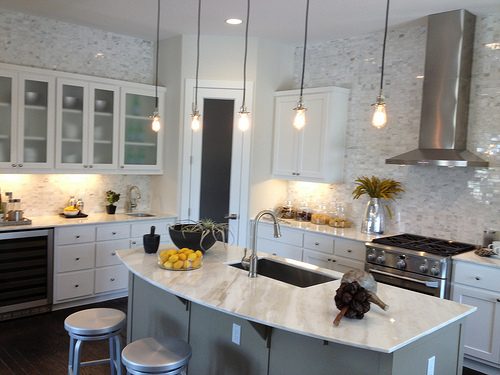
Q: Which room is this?
A: It is a kitchen.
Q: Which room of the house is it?
A: It is a kitchen.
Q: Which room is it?
A: It is a kitchen.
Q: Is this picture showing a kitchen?
A: Yes, it is showing a kitchen.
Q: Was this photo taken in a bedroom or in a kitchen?
A: It was taken at a kitchen.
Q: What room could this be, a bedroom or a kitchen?
A: It is a kitchen.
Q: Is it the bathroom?
A: No, it is the kitchen.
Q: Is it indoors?
A: Yes, it is indoors.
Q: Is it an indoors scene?
A: Yes, it is indoors.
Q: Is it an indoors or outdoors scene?
A: It is indoors.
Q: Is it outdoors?
A: No, it is indoors.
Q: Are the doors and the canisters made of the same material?
A: Yes, both the doors and the canisters are made of glass.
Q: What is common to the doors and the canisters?
A: The material, both the doors and the canisters are glass.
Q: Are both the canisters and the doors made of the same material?
A: Yes, both the canisters and the doors are made of glass.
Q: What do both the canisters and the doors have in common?
A: The material, both the canisters and the doors are glass.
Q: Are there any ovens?
A: Yes, there is an oven.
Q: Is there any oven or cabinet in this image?
A: Yes, there is an oven.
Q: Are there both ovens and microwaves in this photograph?
A: No, there is an oven but no microwaves.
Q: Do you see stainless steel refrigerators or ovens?
A: Yes, there is a stainless steel oven.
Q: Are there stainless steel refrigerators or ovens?
A: Yes, there is a stainless steel oven.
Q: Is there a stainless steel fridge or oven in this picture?
A: Yes, there is a stainless steel oven.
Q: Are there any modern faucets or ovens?
A: Yes, there is a modern oven.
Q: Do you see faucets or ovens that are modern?
A: Yes, the oven is modern.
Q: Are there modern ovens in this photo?
A: Yes, there is a modern oven.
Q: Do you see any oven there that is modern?
A: Yes, there is an oven that is modern.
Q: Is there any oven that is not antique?
A: Yes, there is an modern oven.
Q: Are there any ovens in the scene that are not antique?
A: Yes, there is an modern oven.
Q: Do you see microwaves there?
A: No, there are no microwaves.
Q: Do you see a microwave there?
A: No, there are no microwaves.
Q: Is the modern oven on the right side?
A: Yes, the oven is on the right of the image.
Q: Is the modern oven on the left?
A: No, the oven is on the right of the image.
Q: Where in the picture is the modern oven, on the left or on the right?
A: The oven is on the right of the image.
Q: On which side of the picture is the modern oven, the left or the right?
A: The oven is on the right of the image.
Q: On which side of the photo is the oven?
A: The oven is on the right of the image.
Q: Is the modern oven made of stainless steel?
A: Yes, the oven is made of stainless steel.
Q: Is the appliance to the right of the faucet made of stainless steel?
A: Yes, the oven is made of stainless steel.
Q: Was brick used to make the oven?
A: No, the oven is made of stainless steel.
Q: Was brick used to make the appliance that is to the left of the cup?
A: No, the oven is made of stainless steel.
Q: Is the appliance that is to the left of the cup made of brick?
A: No, the oven is made of stainless steel.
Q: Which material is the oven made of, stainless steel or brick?
A: The oven is made of stainless steel.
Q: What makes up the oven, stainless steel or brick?
A: The oven is made of stainless steel.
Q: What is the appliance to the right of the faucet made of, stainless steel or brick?
A: The oven is made of stainless steel.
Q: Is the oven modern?
A: Yes, the oven is modern.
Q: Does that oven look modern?
A: Yes, the oven is modern.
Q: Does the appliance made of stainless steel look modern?
A: Yes, the oven is modern.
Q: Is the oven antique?
A: No, the oven is modern.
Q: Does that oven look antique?
A: No, the oven is modern.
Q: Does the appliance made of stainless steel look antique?
A: No, the oven is modern.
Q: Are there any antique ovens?
A: No, there is an oven but it is modern.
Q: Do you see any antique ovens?
A: No, there is an oven but it is modern.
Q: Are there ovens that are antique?
A: No, there is an oven but it is modern.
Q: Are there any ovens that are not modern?
A: No, there is an oven but it is modern.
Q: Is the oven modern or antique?
A: The oven is modern.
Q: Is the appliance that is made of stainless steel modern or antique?
A: The oven is modern.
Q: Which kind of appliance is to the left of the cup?
A: The appliance is an oven.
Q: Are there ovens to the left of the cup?
A: Yes, there is an oven to the left of the cup.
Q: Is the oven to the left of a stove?
A: No, the oven is to the left of the cup.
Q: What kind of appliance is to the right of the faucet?
A: The appliance is an oven.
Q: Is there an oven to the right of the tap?
A: Yes, there is an oven to the right of the tap.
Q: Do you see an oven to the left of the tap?
A: No, the oven is to the right of the tap.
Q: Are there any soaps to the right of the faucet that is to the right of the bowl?
A: No, there is an oven to the right of the tap.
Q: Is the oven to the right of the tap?
A: Yes, the oven is to the right of the tap.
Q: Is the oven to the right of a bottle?
A: No, the oven is to the right of the tap.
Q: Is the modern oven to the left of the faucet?
A: No, the oven is to the right of the faucet.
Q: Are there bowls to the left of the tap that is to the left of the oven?
A: Yes, there is a bowl to the left of the tap.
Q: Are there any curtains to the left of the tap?
A: No, there is a bowl to the left of the tap.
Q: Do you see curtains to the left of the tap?
A: No, there is a bowl to the left of the tap.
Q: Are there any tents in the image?
A: No, there are no tents.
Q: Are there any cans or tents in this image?
A: No, there are no tents or cans.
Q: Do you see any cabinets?
A: Yes, there is a cabinet.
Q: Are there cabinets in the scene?
A: Yes, there is a cabinet.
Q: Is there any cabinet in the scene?
A: Yes, there is a cabinet.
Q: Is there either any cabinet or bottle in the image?
A: Yes, there is a cabinet.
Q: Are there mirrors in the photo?
A: No, there are no mirrors.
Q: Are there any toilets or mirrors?
A: No, there are no mirrors or toilets.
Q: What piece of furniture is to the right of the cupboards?
A: The piece of furniture is a cabinet.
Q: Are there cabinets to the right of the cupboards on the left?
A: Yes, there is a cabinet to the right of the cupboards.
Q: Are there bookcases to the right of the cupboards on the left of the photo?
A: No, there is a cabinet to the right of the cupboards.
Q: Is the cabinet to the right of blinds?
A: No, the cabinet is to the right of the cupboards.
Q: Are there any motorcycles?
A: No, there are no motorcycles.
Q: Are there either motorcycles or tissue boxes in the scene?
A: No, there are no motorcycles or tissue boxes.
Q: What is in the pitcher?
A: The plant is in the pitcher.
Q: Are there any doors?
A: Yes, there are doors.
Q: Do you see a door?
A: Yes, there are doors.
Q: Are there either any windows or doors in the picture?
A: Yes, there are doors.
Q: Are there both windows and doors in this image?
A: No, there are doors but no windows.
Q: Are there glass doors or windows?
A: Yes, there are glass doors.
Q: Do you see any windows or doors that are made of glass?
A: Yes, the doors are made of glass.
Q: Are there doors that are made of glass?
A: Yes, there are doors that are made of glass.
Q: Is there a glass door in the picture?
A: Yes, there are doors that are made of glass.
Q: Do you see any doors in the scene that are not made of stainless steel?
A: Yes, there are doors that are made of glass.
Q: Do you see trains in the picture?
A: No, there are no trains.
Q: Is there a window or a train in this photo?
A: No, there are no trains or windows.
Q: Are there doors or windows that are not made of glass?
A: No, there are doors but they are made of glass.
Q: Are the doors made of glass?
A: Yes, the doors are made of glass.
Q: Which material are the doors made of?
A: The doors are made of glass.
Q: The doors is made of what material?
A: The doors are made of glass.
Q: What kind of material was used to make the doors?
A: The doors are made of glass.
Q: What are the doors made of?
A: The doors are made of glass.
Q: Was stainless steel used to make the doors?
A: No, the doors are made of glass.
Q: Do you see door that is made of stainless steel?
A: No, there are doors but they are made of glass.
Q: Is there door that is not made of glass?
A: No, there are doors but they are made of glass.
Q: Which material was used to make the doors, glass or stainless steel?
A: The doors are made of glass.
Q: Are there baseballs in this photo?
A: No, there are no baseballs.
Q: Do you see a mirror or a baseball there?
A: No, there are no baseballs or mirrors.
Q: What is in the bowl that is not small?
A: The plant is in the bowl.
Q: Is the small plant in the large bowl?
A: Yes, the plant is in the bowl.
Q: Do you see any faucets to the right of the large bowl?
A: Yes, there is a faucet to the right of the bowl.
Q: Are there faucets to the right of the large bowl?
A: Yes, there is a faucet to the right of the bowl.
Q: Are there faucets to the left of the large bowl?
A: No, the faucet is to the right of the bowl.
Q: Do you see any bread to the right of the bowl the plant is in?
A: No, there is a faucet to the right of the bowl.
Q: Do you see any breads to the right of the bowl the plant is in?
A: No, there is a faucet to the right of the bowl.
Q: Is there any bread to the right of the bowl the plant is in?
A: No, there is a faucet to the right of the bowl.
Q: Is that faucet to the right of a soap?
A: No, the faucet is to the right of the bowl.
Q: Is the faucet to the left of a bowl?
A: No, the faucet is to the right of a bowl.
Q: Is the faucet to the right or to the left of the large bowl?
A: The faucet is to the right of the bowl.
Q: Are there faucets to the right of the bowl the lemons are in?
A: Yes, there is a faucet to the right of the bowl.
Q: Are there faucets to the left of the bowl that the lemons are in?
A: No, the faucet is to the right of the bowl.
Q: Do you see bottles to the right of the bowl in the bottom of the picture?
A: No, there is a faucet to the right of the bowl.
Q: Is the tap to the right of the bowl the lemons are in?
A: Yes, the tap is to the right of the bowl.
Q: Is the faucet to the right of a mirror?
A: No, the faucet is to the right of the bowl.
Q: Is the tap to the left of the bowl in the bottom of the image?
A: No, the tap is to the right of the bowl.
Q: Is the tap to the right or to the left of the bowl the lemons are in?
A: The tap is to the right of the bowl.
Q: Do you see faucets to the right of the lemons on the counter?
A: Yes, there is a faucet to the right of the lemons.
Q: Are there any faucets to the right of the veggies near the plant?
A: Yes, there is a faucet to the right of the lemons.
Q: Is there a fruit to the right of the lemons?
A: No, there is a faucet to the right of the lemons.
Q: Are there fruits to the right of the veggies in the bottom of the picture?
A: No, there is a faucet to the right of the lemons.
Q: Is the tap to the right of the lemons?
A: Yes, the tap is to the right of the lemons.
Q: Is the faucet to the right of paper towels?
A: No, the faucet is to the right of the lemons.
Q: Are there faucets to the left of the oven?
A: Yes, there is a faucet to the left of the oven.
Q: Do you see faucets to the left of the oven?
A: Yes, there is a faucet to the left of the oven.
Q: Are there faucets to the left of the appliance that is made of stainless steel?
A: Yes, there is a faucet to the left of the oven.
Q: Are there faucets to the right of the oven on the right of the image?
A: No, the faucet is to the left of the oven.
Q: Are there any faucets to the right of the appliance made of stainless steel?
A: No, the faucet is to the left of the oven.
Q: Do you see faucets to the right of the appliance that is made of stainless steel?
A: No, the faucet is to the left of the oven.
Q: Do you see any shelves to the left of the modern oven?
A: No, there is a faucet to the left of the oven.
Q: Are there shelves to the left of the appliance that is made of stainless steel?
A: No, there is a faucet to the left of the oven.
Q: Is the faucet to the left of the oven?
A: Yes, the faucet is to the left of the oven.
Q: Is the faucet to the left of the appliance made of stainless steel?
A: Yes, the faucet is to the left of the oven.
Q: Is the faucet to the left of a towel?
A: No, the faucet is to the left of the oven.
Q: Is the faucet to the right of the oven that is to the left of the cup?
A: No, the faucet is to the left of the oven.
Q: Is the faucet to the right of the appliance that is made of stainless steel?
A: No, the faucet is to the left of the oven.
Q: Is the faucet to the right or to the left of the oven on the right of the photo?
A: The faucet is to the left of the oven.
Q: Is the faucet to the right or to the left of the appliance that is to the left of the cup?
A: The faucet is to the left of the oven.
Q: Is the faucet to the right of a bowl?
A: Yes, the faucet is to the right of a bowl.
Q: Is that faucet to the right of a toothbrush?
A: No, the faucet is to the right of a bowl.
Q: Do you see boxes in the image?
A: No, there are no boxes.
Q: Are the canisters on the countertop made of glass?
A: Yes, the canisters are made of glass.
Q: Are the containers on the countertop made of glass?
A: Yes, the canisters are made of glass.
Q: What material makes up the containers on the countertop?
A: The canisters are made of glass.